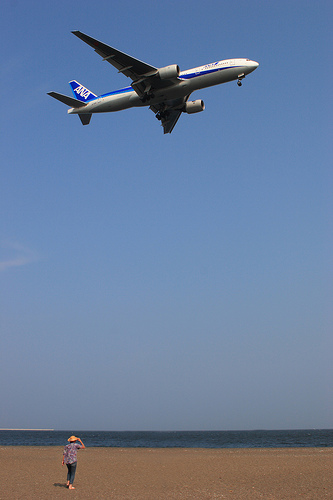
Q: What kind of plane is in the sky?
A: Jet.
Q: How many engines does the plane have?
A: Two.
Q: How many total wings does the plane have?
A: Five.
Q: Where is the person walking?
A: Beach.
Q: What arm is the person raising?
A: Right.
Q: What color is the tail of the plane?
A: Blue.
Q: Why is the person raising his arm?
A: Blocking the sun.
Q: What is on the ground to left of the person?
A: A shadow.